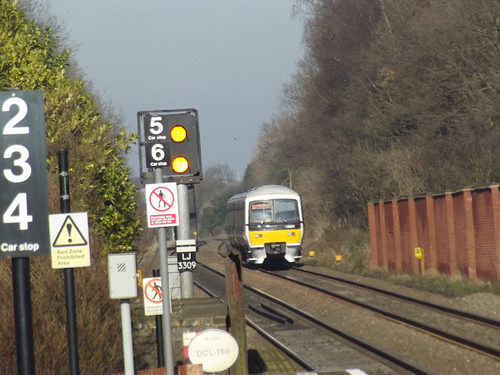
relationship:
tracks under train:
[188, 238, 499, 375] [224, 182, 304, 271]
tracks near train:
[188, 238, 499, 375] [224, 182, 304, 271]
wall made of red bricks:
[366, 183, 499, 290] [366, 184, 498, 290]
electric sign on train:
[250, 203, 272, 211] [224, 182, 304, 271]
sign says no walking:
[146, 182, 179, 230] [150, 186, 175, 211]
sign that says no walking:
[146, 182, 179, 230] [150, 186, 175, 211]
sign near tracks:
[146, 182, 179, 230] [188, 238, 499, 375]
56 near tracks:
[148, 116, 166, 161] [188, 238, 499, 375]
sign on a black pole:
[46, 211, 91, 272] [55, 150, 81, 374]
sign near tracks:
[46, 211, 91, 272] [188, 238, 499, 375]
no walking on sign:
[150, 186, 175, 211] [146, 182, 179, 230]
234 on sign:
[0, 90, 50, 259] [1, 90, 52, 258]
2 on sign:
[2, 98, 30, 137] [1, 90, 52, 258]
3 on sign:
[3, 144, 31, 183] [1, 90, 52, 258]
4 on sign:
[3, 193, 33, 232] [1, 90, 52, 258]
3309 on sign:
[177, 261, 197, 270] [176, 253, 198, 271]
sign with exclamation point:
[46, 211, 91, 272] [66, 222, 76, 244]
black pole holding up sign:
[11, 257, 37, 374] [1, 90, 52, 258]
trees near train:
[0, 1, 499, 374] [224, 182, 304, 271]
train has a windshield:
[224, 182, 304, 271] [249, 199, 302, 231]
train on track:
[224, 182, 304, 271] [189, 239, 434, 375]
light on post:
[170, 127, 187, 143] [137, 109, 202, 299]